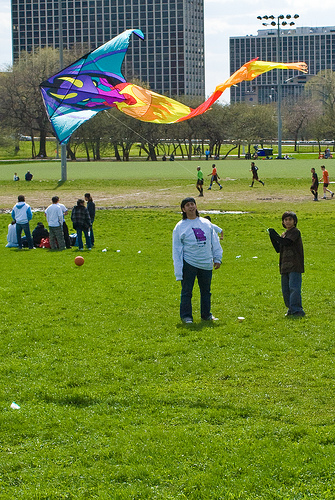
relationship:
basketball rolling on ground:
[71, 255, 83, 266] [8, 154, 328, 490]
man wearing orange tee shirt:
[208, 163, 223, 186] [210, 168, 221, 178]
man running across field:
[245, 156, 260, 186] [107, 155, 325, 234]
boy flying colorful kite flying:
[261, 210, 314, 318] [37, 29, 308, 147]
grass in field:
[29, 238, 333, 493] [18, 138, 325, 497]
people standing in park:
[168, 195, 307, 336] [7, 81, 332, 497]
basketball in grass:
[73, 255, 83, 266] [39, 240, 175, 419]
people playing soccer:
[181, 156, 332, 202] [172, 146, 333, 208]